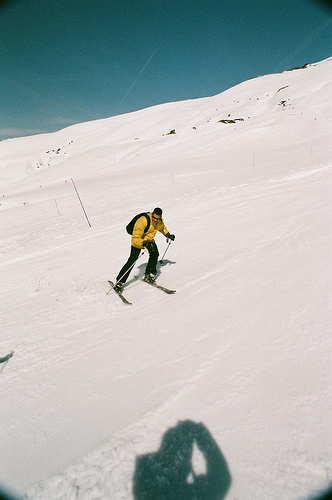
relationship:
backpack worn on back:
[126, 211, 151, 237] [134, 212, 150, 232]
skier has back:
[116, 207, 177, 295] [134, 212, 150, 232]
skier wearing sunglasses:
[116, 207, 177, 295] [151, 214, 161, 222]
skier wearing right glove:
[116, 207, 177, 295] [143, 241, 154, 249]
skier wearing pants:
[116, 207, 177, 295] [116, 241, 160, 281]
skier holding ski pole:
[116, 207, 177, 295] [158, 239, 173, 268]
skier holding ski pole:
[116, 207, 177, 295] [105, 247, 147, 296]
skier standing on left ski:
[116, 207, 177, 295] [132, 274, 177, 295]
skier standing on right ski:
[116, 207, 177, 295] [108, 279, 134, 307]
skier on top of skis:
[116, 207, 177, 295] [107, 274, 177, 305]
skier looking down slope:
[116, 207, 177, 295] [0, 55, 331, 498]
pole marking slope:
[69, 177, 93, 228] [0, 55, 331, 498]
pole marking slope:
[51, 195, 62, 218] [0, 55, 331, 498]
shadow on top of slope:
[132, 419, 232, 500] [0, 55, 331, 498]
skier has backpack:
[116, 207, 177, 295] [126, 211, 151, 237]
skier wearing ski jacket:
[116, 207, 177, 295] [132, 213, 170, 249]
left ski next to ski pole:
[132, 274, 177, 295] [158, 239, 173, 268]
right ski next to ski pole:
[108, 279, 134, 307] [105, 247, 147, 296]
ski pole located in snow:
[158, 239, 173, 268] [0, 56, 331, 499]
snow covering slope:
[0, 56, 331, 499] [0, 55, 331, 498]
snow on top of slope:
[0, 56, 331, 499] [0, 55, 331, 498]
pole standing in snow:
[69, 177, 93, 228] [0, 56, 331, 499]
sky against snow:
[0, 2, 330, 143] [0, 56, 331, 499]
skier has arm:
[116, 207, 177, 295] [131, 218, 154, 248]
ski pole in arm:
[105, 247, 147, 296] [131, 218, 154, 248]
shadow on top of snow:
[132, 419, 232, 500] [0, 56, 331, 499]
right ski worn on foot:
[108, 279, 134, 307] [115, 283, 123, 293]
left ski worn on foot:
[132, 274, 177, 295] [143, 276, 155, 286]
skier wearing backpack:
[116, 207, 177, 295] [126, 211, 151, 237]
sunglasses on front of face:
[151, 214, 161, 222] [151, 212, 161, 226]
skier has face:
[116, 207, 177, 295] [151, 212, 161, 226]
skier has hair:
[116, 207, 177, 295] [151, 207, 162, 214]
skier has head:
[116, 207, 177, 295] [151, 207, 163, 227]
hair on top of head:
[151, 207, 162, 214] [151, 207, 163, 227]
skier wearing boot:
[116, 207, 177, 295] [115, 282, 122, 293]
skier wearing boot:
[116, 207, 177, 295] [143, 274, 157, 285]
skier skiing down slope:
[116, 207, 177, 295] [0, 55, 331, 498]